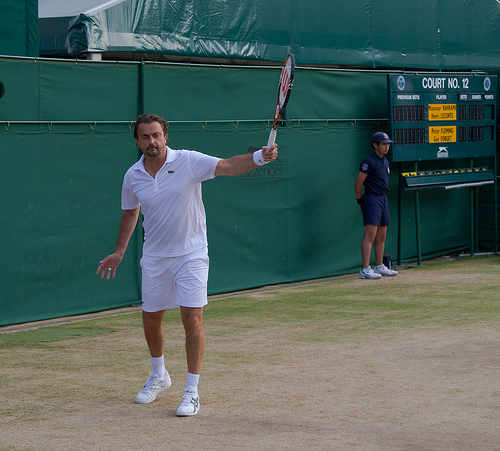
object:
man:
[96, 114, 278, 417]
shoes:
[174, 392, 199, 417]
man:
[354, 132, 400, 279]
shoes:
[359, 266, 382, 280]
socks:
[150, 355, 166, 379]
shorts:
[139, 247, 211, 313]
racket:
[266, 53, 294, 149]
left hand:
[262, 143, 278, 162]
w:
[280, 69, 291, 96]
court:
[1, 1, 496, 450]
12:
[462, 78, 470, 89]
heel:
[157, 372, 171, 391]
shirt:
[120, 150, 223, 258]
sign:
[428, 102, 457, 122]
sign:
[427, 125, 455, 142]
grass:
[0, 254, 499, 451]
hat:
[371, 131, 394, 143]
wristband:
[252, 148, 270, 167]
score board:
[385, 70, 497, 264]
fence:
[3, 53, 496, 328]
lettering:
[397, 74, 493, 101]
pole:
[135, 61, 146, 295]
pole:
[383, 73, 391, 136]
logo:
[167, 169, 175, 173]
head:
[277, 52, 296, 114]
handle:
[266, 128, 276, 151]